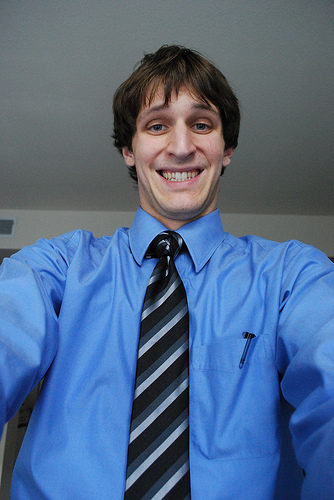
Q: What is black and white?
A: Tie.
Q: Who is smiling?
A: The man.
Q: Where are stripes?
A: On man's tie.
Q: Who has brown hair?
A: The man.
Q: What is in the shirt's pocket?
A: A pen.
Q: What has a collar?
A: Blue shirt.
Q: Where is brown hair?
A: On man's head.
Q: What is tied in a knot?
A: The tie.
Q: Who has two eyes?
A: Man smiling.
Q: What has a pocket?
A: The blue shirt.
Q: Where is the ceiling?
A: Behind man's head.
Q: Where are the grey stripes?
A: On the tie.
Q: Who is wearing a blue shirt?
A: The man.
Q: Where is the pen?
A: In the shirt pocket.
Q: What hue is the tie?
A: Black and gray.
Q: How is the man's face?
A: Smiling.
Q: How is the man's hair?
A: Shaggy.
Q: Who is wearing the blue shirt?
A: The man.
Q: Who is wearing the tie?
A: The man.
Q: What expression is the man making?
A: Smiling.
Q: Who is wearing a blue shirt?
A: The man.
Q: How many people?
A: 1.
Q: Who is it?
A: A man.